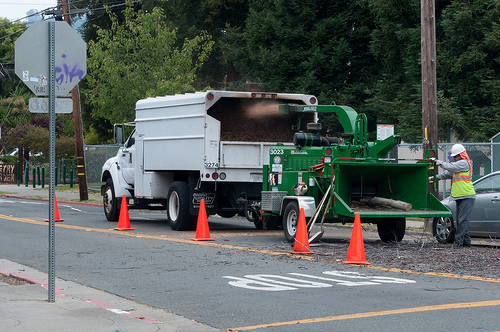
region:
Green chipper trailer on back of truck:
[263, 101, 428, 212]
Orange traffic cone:
[341, 210, 362, 267]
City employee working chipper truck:
[442, 143, 474, 250]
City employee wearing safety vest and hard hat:
[442, 142, 477, 202]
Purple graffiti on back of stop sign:
[14, 20, 84, 95]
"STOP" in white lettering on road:
[220, 269, 402, 296]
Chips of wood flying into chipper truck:
[242, 100, 282, 119]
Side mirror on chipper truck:
[112, 121, 127, 148]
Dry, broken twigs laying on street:
[372, 240, 495, 272]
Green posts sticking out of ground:
[12, 158, 43, 188]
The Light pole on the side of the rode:
[408, 75, 431, 97]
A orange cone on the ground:
[359, 245, 373, 260]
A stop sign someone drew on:
[68, 70, 83, 91]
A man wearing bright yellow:
[461, 180, 481, 197]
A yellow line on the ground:
[255, 315, 275, 330]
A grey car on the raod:
[476, 223, 498, 244]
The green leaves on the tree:
[197, 50, 221, 69]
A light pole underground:
[77, 126, 89, 143]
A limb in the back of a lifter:
[396, 198, 415, 212]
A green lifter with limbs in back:
[428, 206, 444, 221]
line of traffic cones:
[108, 188, 372, 267]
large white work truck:
[93, 85, 258, 225]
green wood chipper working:
[248, 98, 428, 231]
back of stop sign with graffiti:
[11, 10, 88, 127]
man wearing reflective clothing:
[433, 138, 476, 250]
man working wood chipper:
[323, 128, 483, 245]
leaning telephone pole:
[63, 89, 96, 205]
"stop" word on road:
[210, 262, 427, 302]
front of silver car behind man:
[430, 173, 496, 243]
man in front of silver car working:
[430, 134, 499, 257]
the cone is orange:
[40, 185, 80, 231]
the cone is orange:
[185, 189, 220, 247]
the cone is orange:
[285, 197, 319, 277]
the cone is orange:
[338, 203, 391, 293]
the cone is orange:
[195, 185, 212, 260]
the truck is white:
[74, 74, 354, 254]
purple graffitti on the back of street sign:
[50, 64, 84, 85]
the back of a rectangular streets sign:
[22, 94, 74, 115]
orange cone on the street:
[337, 210, 369, 265]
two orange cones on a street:
[290, 205, 377, 265]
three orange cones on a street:
[191, 194, 376, 266]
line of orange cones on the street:
[45, 187, 376, 267]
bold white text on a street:
[215, 261, 423, 293]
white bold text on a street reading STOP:
[214, 265, 428, 293]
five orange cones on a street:
[50, 187, 372, 267]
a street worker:
[424, 138, 482, 246]